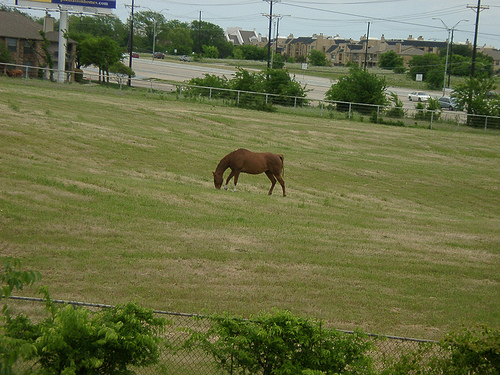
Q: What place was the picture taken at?
A: It was taken at the field.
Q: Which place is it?
A: It is a field.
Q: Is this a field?
A: Yes, it is a field.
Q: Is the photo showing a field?
A: Yes, it is showing a field.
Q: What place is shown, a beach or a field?
A: It is a field.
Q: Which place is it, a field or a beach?
A: It is a field.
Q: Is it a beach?
A: No, it is a field.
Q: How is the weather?
A: It is overcast.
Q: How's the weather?
A: It is overcast.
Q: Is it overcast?
A: Yes, it is overcast.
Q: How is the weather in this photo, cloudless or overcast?
A: It is overcast.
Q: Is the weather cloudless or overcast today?
A: It is overcast.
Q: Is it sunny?
A: No, it is overcast.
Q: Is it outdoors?
A: Yes, it is outdoors.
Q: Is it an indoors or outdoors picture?
A: It is outdoors.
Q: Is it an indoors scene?
A: No, it is outdoors.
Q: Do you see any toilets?
A: No, there are no toilets.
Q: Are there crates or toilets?
A: No, there are no toilets or crates.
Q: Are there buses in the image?
A: No, there are no buses.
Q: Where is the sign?
A: The sign is on the highway.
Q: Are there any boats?
A: No, there are no boats.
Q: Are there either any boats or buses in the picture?
A: No, there are no boats or buses.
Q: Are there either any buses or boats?
A: No, there are no boats or buses.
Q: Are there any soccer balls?
A: No, there are no soccer balls.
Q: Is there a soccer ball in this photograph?
A: No, there are no soccer balls.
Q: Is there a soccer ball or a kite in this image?
A: No, there are no soccer balls or kites.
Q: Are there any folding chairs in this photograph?
A: No, there are no folding chairs.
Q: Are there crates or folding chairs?
A: No, there are no folding chairs or crates.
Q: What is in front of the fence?
A: The shrub is in front of the fence.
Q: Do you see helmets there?
A: No, there are no helmets.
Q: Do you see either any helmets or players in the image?
A: No, there are no helmets or players.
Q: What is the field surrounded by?
A: The field is surrounded by the fence.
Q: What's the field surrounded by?
A: The field is surrounded by the fence.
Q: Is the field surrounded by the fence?
A: Yes, the field is surrounded by the fence.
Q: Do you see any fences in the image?
A: Yes, there is a fence.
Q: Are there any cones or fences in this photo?
A: Yes, there is a fence.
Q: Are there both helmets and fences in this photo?
A: No, there is a fence but no helmets.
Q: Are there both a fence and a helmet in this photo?
A: No, there is a fence but no helmets.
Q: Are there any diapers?
A: No, there are no diapers.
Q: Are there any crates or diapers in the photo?
A: No, there are no diapers or crates.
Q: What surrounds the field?
A: The fence surrounds the field.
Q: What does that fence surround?
A: The fence surrounds the field.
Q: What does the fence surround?
A: The fence surrounds the field.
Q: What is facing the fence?
A: The trees are facing the fence.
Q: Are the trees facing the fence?
A: Yes, the trees are facing the fence.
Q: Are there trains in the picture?
A: No, there are no trains.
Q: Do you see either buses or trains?
A: No, there are no trains or buses.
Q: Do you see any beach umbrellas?
A: No, there are no beach umbrellas.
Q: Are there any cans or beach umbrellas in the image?
A: No, there are no beach umbrellas or cans.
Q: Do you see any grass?
A: Yes, there is grass.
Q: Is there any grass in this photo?
A: Yes, there is grass.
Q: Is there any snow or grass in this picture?
A: Yes, there is grass.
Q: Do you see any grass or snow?
A: Yes, there is grass.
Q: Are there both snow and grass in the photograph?
A: No, there is grass but no snow.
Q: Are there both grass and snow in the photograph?
A: No, there is grass but no snow.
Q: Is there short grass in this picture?
A: Yes, there is short grass.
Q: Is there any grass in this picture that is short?
A: Yes, there is grass that is short.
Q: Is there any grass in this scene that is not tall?
A: Yes, there is short grass.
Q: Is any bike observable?
A: No, there are no bikes.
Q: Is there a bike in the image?
A: No, there are no bikes.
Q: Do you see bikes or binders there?
A: No, there are no bikes or binders.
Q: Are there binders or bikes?
A: No, there are no bikes or binders.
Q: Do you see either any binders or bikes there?
A: No, there are no bikes or binders.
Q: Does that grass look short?
A: Yes, the grass is short.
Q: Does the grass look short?
A: Yes, the grass is short.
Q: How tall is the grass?
A: The grass is short.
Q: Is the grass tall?
A: No, the grass is short.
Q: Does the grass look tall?
A: No, the grass is short.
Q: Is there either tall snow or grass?
A: No, there is grass but it is short.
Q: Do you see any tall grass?
A: No, there is grass but it is short.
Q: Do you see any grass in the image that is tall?
A: No, there is grass but it is short.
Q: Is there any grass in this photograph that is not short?
A: No, there is grass but it is short.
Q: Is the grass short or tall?
A: The grass is short.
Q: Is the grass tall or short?
A: The grass is short.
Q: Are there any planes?
A: No, there are no planes.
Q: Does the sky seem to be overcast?
A: Yes, the sky is overcast.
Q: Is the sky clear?
A: No, the sky is overcast.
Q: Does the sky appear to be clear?
A: No, the sky is overcast.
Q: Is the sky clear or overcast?
A: The sky is overcast.